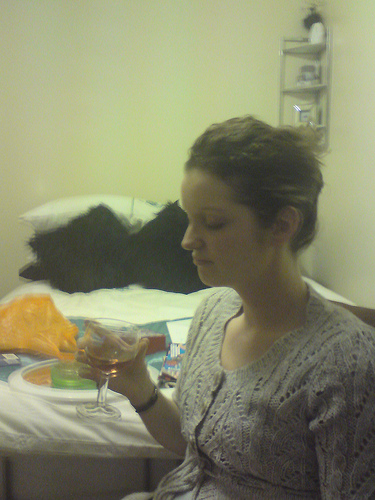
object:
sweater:
[168, 264, 334, 472]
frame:
[285, 87, 333, 154]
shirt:
[152, 301, 363, 459]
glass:
[74, 317, 140, 422]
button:
[199, 398, 208, 416]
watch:
[121, 383, 178, 418]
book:
[157, 342, 188, 387]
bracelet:
[133, 373, 161, 425]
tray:
[9, 337, 148, 448]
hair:
[177, 109, 332, 255]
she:
[77, 115, 375, 500]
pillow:
[19, 195, 160, 232]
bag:
[0, 289, 78, 362]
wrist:
[120, 371, 165, 419]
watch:
[133, 383, 160, 412]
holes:
[278, 375, 312, 407]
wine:
[86, 355, 120, 378]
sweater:
[151, 285, 373, 497]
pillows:
[20, 200, 200, 295]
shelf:
[277, 27, 331, 151]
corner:
[283, 9, 334, 286]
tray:
[6, 361, 158, 406]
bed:
[1, 280, 215, 498]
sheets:
[1, 272, 198, 456]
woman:
[75, 115, 373, 498]